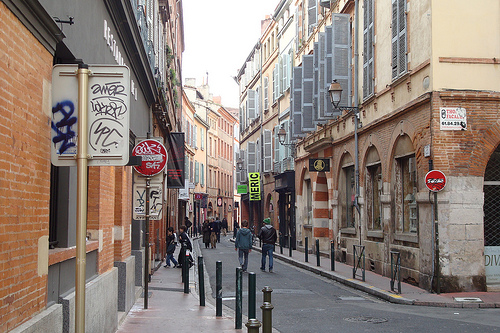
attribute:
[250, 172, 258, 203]
writing — black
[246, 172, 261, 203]
sign — yellow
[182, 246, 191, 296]
post — black, metal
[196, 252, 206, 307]
pole — green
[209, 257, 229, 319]
post — green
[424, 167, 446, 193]
caution sign — round, red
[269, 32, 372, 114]
windows — open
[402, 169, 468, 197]
sign — round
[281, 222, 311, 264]
post — green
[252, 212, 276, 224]
hat — green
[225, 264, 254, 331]
post — green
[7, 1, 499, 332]
buildings — brick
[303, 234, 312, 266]
post — green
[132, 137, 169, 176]
sign — round, red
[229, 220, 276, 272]
men — standing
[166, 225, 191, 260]
people — standing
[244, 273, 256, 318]
post — green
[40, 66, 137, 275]
windows — arched